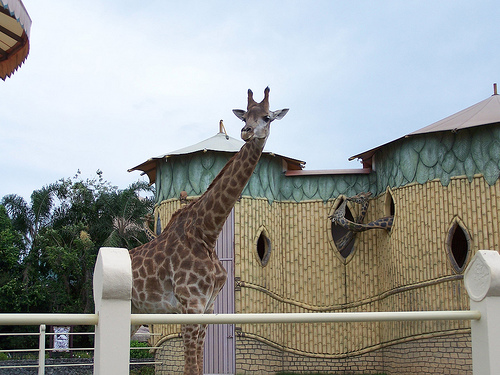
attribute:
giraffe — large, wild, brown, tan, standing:
[128, 87, 288, 369]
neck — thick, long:
[199, 142, 256, 237]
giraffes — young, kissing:
[331, 193, 394, 259]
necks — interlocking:
[343, 221, 392, 258]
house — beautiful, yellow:
[140, 121, 500, 364]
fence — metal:
[5, 244, 498, 374]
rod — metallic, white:
[37, 324, 52, 375]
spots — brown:
[164, 231, 181, 260]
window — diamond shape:
[328, 196, 358, 255]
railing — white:
[2, 298, 498, 333]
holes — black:
[244, 126, 252, 132]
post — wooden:
[36, 324, 45, 374]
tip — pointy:
[213, 118, 227, 137]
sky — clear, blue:
[1, 2, 495, 123]